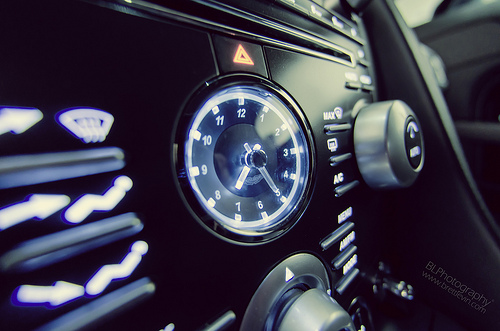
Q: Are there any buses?
A: No, there are no buses.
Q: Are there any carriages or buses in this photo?
A: No, there are no buses or carriages.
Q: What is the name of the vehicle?
A: The vehicle is a car.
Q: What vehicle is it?
A: The vehicle is a car.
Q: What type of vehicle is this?
A: This is a car.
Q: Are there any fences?
A: No, there are no fences.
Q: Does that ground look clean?
A: Yes, the ground is clean.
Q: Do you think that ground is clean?
A: Yes, the ground is clean.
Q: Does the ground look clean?
A: Yes, the ground is clean.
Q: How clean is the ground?
A: The ground is clean.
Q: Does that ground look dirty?
A: No, the ground is clean.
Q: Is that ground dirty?
A: No, the ground is clean.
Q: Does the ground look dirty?
A: No, the ground is clean.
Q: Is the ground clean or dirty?
A: The ground is clean.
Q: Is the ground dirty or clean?
A: The ground is clean.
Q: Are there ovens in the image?
A: No, there are no ovens.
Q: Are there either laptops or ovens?
A: No, there are no ovens or laptops.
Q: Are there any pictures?
A: No, there are no pictures.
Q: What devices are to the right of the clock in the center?
A: The devices are controllers.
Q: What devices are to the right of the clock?
A: The devices are controllers.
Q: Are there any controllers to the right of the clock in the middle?
A: Yes, there are controllers to the right of the clock.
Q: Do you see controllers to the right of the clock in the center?
A: Yes, there are controllers to the right of the clock.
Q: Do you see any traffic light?
A: No, there are no traffic lights.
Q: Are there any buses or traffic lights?
A: No, there are no traffic lights or buses.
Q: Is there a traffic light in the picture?
A: No, there are no traffic lights.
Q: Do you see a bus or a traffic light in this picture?
A: No, there are no traffic lights or buses.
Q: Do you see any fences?
A: No, there are no fences.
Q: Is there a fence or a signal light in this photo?
A: No, there are no fences or traffic lights.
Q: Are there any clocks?
A: Yes, there is a clock.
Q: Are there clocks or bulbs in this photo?
A: Yes, there is a clock.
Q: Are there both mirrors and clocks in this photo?
A: No, there is a clock but no mirrors.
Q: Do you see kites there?
A: No, there are no kites.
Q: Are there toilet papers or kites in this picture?
A: No, there are no kites or toilet papers.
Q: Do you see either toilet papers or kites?
A: No, there are no kites or toilet papers.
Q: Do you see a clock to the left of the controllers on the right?
A: Yes, there is a clock to the left of the controllers.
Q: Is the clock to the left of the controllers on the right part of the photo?
A: Yes, the clock is to the left of the controllers.